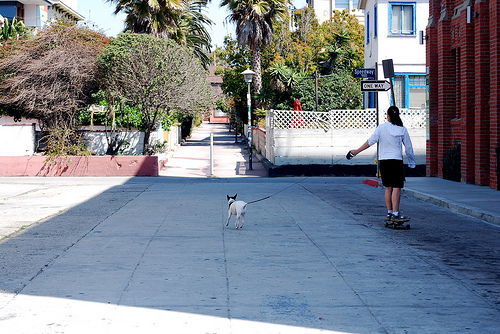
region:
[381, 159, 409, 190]
the shorts are black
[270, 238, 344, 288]
the ground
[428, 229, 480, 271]
stains on the ground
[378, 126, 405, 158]
white shirt the person is wearing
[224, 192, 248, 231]
a small white dog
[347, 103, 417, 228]
a woman on a skateboard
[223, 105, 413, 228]
a woman walking a dog on a skateboard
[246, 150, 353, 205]
a black dog leash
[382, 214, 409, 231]
a worn skateboard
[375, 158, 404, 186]
a pair of black shorts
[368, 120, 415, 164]
a white hooded sweatshirt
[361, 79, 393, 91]
a ONE WAY traffic sign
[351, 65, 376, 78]
a street name sign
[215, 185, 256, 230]
this is a dog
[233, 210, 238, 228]
this is a dog's leg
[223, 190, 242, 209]
this is a dog's head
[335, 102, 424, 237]
this is a person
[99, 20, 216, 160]
this is a tall tree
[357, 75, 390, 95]
this is a sign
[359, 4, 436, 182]
this is a building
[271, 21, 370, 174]
this is green vegetation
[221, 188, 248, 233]
WHITE AND BLACK DOG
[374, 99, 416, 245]
LADY ON A SKATEBOARD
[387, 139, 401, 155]
WOMAN HAS ON A WHITE JACKET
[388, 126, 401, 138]
LADY HAS A HOOD ON THE BACK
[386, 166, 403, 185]
LADY HAS ON A SKIRT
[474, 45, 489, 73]
BUILDING MADE OF RED BRICKS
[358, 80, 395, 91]
SIGN WITH AAROW POINTING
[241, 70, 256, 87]
LIGHT ON A POLE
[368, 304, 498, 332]
white square on concrete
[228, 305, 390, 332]
white square on concrete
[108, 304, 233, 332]
white square on concrete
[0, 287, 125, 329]
white square on concrete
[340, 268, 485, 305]
white square on concrete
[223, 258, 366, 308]
white square on concrete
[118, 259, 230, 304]
white square on concrete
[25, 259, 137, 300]
white square on concrete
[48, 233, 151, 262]
white square on concrete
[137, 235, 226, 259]
white square on concrete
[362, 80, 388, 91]
a one way sign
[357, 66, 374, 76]
name of the street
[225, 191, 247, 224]
black and white dog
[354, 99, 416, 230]
girl on the skateboard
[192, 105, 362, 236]
dog on a leash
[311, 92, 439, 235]
woman on a skateboard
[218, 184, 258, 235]
the dog is white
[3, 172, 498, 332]
shadow on the ground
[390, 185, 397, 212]
leg of a woman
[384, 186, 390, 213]
leg of a woman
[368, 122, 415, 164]
the shirt is white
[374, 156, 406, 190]
the shorts are black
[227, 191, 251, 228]
the dog is small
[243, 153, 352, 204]
the leash is black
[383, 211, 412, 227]
skate board on ground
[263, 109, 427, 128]
the fence is white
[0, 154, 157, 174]
the wall is red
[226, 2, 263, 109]
A tree in a city.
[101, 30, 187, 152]
A tree in a city.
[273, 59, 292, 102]
A tree in a city.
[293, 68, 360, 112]
A tree in a city.